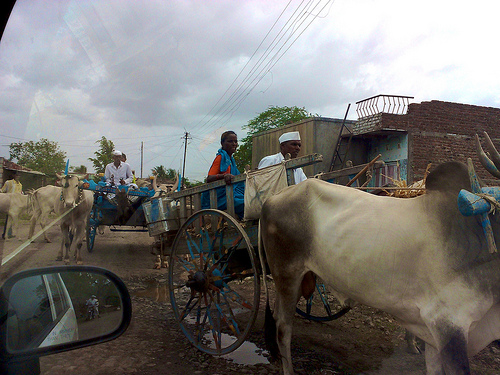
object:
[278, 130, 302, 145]
hat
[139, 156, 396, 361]
cart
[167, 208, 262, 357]
wheel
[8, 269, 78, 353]
vehicle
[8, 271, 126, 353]
mirror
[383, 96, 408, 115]
rail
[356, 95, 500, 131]
roof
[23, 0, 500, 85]
sky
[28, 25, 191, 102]
clouds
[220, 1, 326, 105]
wires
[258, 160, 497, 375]
animal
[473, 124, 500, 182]
antlers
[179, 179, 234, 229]
railing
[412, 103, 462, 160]
wall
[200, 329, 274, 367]
puddle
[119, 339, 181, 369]
ground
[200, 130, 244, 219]
people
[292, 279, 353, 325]
wheels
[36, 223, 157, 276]
road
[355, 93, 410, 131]
balcony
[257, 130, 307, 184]
man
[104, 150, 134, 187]
man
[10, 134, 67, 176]
trees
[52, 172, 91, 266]
oxen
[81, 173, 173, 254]
cart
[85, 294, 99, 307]
person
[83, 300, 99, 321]
bike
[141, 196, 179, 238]
pail